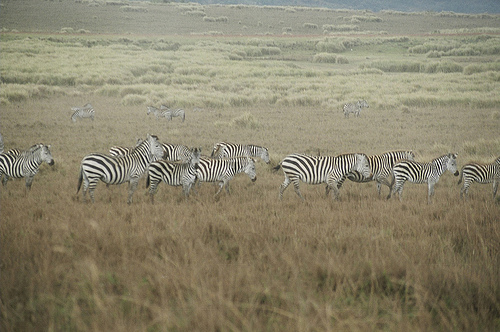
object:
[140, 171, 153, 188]
tufts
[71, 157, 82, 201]
tufts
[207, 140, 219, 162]
tufts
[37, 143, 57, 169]
head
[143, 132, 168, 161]
head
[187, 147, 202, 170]
head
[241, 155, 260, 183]
head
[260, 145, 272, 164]
head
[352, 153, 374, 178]
head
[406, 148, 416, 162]
head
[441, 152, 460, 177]
head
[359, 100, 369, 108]
head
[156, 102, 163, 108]
head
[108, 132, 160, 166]
zebra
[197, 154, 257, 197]
zebra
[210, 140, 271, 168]
zebra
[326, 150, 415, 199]
zebra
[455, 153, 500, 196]
zebra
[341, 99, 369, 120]
zebra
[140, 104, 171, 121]
zebra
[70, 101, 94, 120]
zebra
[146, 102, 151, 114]
head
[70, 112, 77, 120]
head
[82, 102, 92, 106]
head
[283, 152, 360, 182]
stripes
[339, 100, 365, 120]
zebra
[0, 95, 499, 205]
heard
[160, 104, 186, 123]
zebras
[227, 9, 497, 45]
river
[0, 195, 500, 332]
grass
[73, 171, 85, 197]
tail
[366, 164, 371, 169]
eye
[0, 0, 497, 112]
bushes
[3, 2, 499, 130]
vegetation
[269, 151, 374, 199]
zebra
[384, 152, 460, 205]
zebra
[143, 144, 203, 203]
zebra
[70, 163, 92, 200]
tip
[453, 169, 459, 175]
black nose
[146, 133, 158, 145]
ear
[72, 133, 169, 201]
zebra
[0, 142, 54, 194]
zebra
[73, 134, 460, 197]
herd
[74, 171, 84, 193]
hair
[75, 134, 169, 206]
zebra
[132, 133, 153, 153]
mane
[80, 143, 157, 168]
back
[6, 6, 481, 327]
field